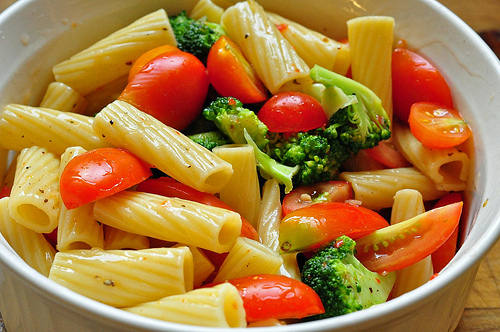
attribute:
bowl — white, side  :
[3, 3, 497, 330]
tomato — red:
[59, 145, 148, 207]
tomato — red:
[228, 269, 320, 319]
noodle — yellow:
[88, 98, 240, 194]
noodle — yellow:
[87, 190, 246, 254]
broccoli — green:
[274, 111, 369, 191]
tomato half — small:
[396, 101, 473, 159]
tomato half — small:
[247, 83, 333, 140]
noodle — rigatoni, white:
[44, 247, 200, 311]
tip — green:
[278, 218, 324, 257]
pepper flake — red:
[223, 96, 239, 109]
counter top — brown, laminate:
[447, 269, 483, 330]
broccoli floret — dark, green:
[163, 9, 225, 56]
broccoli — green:
[190, 64, 396, 186]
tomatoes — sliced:
[113, 31, 266, 127]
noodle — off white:
[79, 91, 233, 197]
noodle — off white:
[1, 92, 112, 160]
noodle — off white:
[2, 139, 70, 248]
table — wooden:
[455, 272, 484, 330]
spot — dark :
[469, 292, 484, 309]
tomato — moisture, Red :
[131, 47, 211, 117]